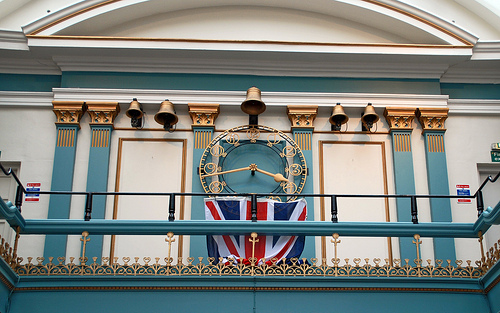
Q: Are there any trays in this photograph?
A: No, there are no trays.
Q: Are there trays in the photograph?
A: No, there are no trays.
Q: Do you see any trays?
A: No, there are no trays.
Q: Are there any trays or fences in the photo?
A: No, there are no trays or fences.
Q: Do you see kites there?
A: No, there are no kites.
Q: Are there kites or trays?
A: No, there are no kites or trays.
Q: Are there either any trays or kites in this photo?
A: No, there are no kites or trays.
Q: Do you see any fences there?
A: No, there are no fences.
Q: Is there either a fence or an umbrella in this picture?
A: No, there are no fences or umbrellas.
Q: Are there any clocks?
A: Yes, there is a clock.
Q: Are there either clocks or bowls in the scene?
A: Yes, there is a clock.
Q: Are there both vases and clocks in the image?
A: No, there is a clock but no vases.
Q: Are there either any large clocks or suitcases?
A: Yes, there is a large clock.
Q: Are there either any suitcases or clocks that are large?
A: Yes, the clock is large.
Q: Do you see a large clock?
A: Yes, there is a large clock.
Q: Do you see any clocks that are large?
A: Yes, there is a clock that is large.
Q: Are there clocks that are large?
A: Yes, there is a clock that is large.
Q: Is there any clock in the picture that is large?
A: Yes, there is a clock that is large.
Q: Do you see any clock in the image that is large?
A: Yes, there is a clock that is large.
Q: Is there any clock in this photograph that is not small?
A: Yes, there is a large clock.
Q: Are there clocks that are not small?
A: Yes, there is a large clock.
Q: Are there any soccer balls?
A: No, there are no soccer balls.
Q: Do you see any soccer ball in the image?
A: No, there are no soccer balls.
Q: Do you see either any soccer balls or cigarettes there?
A: No, there are no soccer balls or cigarettes.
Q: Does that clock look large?
A: Yes, the clock is large.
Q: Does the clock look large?
A: Yes, the clock is large.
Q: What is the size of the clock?
A: The clock is large.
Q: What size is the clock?
A: The clock is large.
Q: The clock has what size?
A: The clock is large.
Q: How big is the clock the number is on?
A: The clock is large.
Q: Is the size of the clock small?
A: No, the clock is large.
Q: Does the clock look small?
A: No, the clock is large.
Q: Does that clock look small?
A: No, the clock is large.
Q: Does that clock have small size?
A: No, the clock is large.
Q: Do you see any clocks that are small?
A: No, there is a clock but it is large.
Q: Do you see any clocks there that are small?
A: No, there is a clock but it is large.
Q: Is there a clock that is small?
A: No, there is a clock but it is large.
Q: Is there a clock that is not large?
A: No, there is a clock but it is large.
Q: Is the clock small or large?
A: The clock is large.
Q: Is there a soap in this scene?
A: No, there are no soaps.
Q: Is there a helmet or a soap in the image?
A: No, there are no soaps or helmets.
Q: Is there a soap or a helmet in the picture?
A: No, there are no soaps or helmets.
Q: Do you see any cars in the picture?
A: No, there are no cars.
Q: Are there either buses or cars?
A: No, there are no cars or buses.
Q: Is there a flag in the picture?
A: Yes, there is a flag.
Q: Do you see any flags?
A: Yes, there is a flag.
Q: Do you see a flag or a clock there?
A: Yes, there is a flag.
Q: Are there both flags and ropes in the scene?
A: No, there is a flag but no ropes.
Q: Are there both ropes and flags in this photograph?
A: No, there is a flag but no ropes.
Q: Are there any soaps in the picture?
A: No, there are no soaps.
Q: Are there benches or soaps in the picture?
A: No, there are no soaps or benches.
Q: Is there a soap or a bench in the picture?
A: No, there are no soaps or benches.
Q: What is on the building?
A: The flag is on the building.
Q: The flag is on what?
A: The flag is on the building.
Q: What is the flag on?
A: The flag is on the building.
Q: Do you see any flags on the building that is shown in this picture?
A: Yes, there is a flag on the building.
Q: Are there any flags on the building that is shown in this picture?
A: Yes, there is a flag on the building.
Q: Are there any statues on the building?
A: No, there is a flag on the building.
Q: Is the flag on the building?
A: Yes, the flag is on the building.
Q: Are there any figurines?
A: No, there are no figurines.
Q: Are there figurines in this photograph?
A: No, there are no figurines.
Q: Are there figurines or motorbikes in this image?
A: No, there are no figurines or motorbikes.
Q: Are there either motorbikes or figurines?
A: No, there are no figurines or motorbikes.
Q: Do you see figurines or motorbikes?
A: No, there are no figurines or motorbikes.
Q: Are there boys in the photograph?
A: No, there are no boys.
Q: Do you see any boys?
A: No, there are no boys.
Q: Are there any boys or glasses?
A: No, there are no boys or glasses.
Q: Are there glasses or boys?
A: No, there are no boys or glasses.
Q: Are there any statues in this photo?
A: No, there are no statues.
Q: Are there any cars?
A: No, there are no cars.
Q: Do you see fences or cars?
A: No, there are no cars or fences.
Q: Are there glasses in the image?
A: No, there are no glasses.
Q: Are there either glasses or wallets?
A: No, there are no glasses or wallets.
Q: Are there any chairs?
A: No, there are no chairs.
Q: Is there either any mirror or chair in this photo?
A: No, there are no chairs or mirrors.